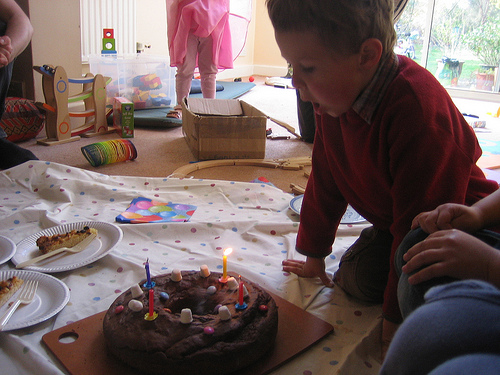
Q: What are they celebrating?
A: Birthday.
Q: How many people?
A: 5.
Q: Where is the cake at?
A: On the blanket.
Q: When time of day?
A: Daytime.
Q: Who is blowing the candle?
A: Boy.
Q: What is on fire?
A: Candle.